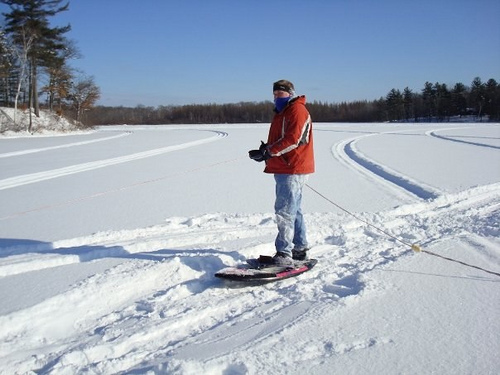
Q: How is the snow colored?
A: White.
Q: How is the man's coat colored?
A: Orange.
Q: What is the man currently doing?
A: Snowboarding.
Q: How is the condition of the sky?
A: Clear and sunny.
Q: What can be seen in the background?
A: Forest.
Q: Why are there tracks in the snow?
A: People may have been skiing or snowboarding.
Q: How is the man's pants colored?
A: Light blue.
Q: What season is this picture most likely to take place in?
A: Winter.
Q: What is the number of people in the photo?
A: One.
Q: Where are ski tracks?
A: In the snow.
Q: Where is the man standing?
A: In snow.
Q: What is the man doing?
A: Snowboarding.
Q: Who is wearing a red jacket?
A: Snowboarder.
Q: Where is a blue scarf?
A: Over man's face.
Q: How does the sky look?
A: Clear and blue.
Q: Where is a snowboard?
A: Under man's feet.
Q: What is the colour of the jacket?
A: Red.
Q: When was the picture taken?
A: Daytime.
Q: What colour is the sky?
A: Blue.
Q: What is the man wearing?
A: Gloves.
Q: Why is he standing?
A: He is getting ready to skate.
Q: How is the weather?
A: Sunny.